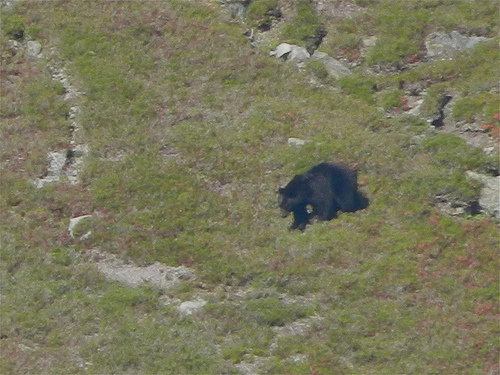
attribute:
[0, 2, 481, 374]
hill — grassy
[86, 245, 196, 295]
dirt — small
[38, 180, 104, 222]
grass — Brown 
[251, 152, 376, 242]
bear — walking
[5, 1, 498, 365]
grass — green , patchy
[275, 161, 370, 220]
bear — Black 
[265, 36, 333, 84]
rock — large 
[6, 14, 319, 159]
grass — green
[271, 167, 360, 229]
bear — black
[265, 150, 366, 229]
bear — black , fuzzy 